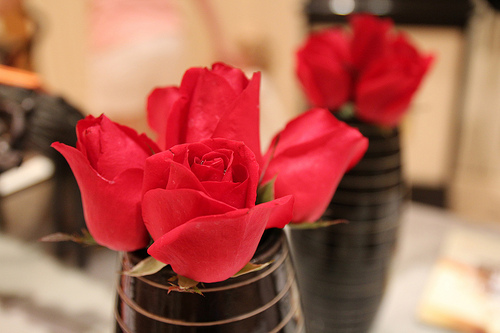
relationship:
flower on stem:
[263, 121, 344, 219] [256, 177, 279, 206]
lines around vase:
[118, 248, 293, 294] [116, 235, 303, 333]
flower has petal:
[263, 121, 344, 219] [313, 134, 359, 183]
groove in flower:
[296, 148, 335, 173] [263, 121, 344, 219]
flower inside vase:
[263, 121, 344, 219] [116, 235, 303, 333]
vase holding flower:
[116, 235, 303, 333] [263, 121, 344, 219]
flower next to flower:
[263, 121, 344, 219] [153, 139, 279, 285]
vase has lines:
[288, 111, 410, 331] [335, 183, 401, 253]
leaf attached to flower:
[287, 216, 349, 235] [263, 121, 344, 219]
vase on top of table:
[116, 235, 303, 333] [13, 198, 500, 329]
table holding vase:
[13, 198, 500, 329] [116, 235, 303, 333]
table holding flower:
[13, 198, 500, 329] [263, 121, 344, 219]